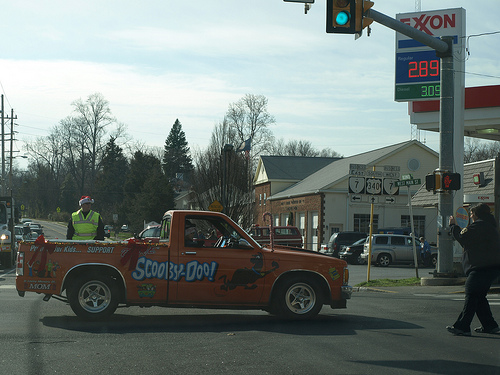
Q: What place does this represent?
A: It represents the road.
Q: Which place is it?
A: It is a road.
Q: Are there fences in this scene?
A: No, there are no fences.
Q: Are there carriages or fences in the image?
A: No, there are no fences or carriages.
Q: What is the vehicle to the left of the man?
A: The vehicle is a car.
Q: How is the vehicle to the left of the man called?
A: The vehicle is a car.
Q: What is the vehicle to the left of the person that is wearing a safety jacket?
A: The vehicle is a car.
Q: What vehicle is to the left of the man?
A: The vehicle is a car.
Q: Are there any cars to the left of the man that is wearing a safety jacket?
A: Yes, there is a car to the left of the man.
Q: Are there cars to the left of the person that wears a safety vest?
A: Yes, there is a car to the left of the man.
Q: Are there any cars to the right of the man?
A: No, the car is to the left of the man.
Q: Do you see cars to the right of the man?
A: No, the car is to the left of the man.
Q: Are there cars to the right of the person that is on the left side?
A: No, the car is to the left of the man.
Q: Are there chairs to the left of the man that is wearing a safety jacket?
A: No, there is a car to the left of the man.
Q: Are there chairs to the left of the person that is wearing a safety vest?
A: No, there is a car to the left of the man.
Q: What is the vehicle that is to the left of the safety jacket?
A: The vehicle is a car.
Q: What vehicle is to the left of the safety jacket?
A: The vehicle is a car.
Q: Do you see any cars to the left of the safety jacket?
A: Yes, there is a car to the left of the safety jacket.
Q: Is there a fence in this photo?
A: No, there are no fences.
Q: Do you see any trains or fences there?
A: No, there are no fences or trains.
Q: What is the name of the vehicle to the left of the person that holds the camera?
A: The vehicle is a car.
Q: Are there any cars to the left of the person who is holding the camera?
A: Yes, there is a car to the left of the person.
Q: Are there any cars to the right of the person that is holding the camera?
A: No, the car is to the left of the person.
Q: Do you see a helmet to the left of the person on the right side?
A: No, there is a car to the left of the person.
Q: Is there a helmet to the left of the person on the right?
A: No, there is a car to the left of the person.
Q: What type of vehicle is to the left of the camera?
A: The vehicle is a car.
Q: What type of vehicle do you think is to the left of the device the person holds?
A: The vehicle is a car.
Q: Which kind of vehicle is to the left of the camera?
A: The vehicle is a car.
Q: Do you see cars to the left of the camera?
A: Yes, there is a car to the left of the camera.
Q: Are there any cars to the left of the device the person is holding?
A: Yes, there is a car to the left of the camera.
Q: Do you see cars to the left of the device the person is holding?
A: Yes, there is a car to the left of the camera.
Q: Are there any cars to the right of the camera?
A: No, the car is to the left of the camera.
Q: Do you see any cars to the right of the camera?
A: No, the car is to the left of the camera.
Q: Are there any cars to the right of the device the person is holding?
A: No, the car is to the left of the camera.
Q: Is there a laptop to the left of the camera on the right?
A: No, there is a car to the left of the camera.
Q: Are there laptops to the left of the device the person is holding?
A: No, there is a car to the left of the camera.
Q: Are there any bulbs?
A: No, there are no bulbs.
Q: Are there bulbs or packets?
A: No, there are no bulbs or packets.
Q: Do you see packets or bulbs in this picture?
A: No, there are no bulbs or packets.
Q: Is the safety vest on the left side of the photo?
A: Yes, the safety vest is on the left of the image.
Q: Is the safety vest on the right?
A: No, the safety vest is on the left of the image.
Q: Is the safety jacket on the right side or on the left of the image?
A: The safety jacket is on the left of the image.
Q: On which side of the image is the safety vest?
A: The safety vest is on the left of the image.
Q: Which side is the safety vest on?
A: The safety vest is on the left of the image.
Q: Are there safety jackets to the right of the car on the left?
A: Yes, there is a safety jacket to the right of the car.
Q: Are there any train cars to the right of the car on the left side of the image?
A: No, there is a safety jacket to the right of the car.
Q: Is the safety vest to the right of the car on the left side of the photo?
A: Yes, the safety vest is to the right of the car.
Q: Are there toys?
A: No, there are no toys.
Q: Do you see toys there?
A: No, there are no toys.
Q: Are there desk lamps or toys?
A: No, there are no toys or desk lamps.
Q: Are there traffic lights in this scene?
A: Yes, there is a traffic light.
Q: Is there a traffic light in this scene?
A: Yes, there is a traffic light.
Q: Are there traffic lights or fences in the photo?
A: Yes, there is a traffic light.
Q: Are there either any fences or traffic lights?
A: Yes, there is a traffic light.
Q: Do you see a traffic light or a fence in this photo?
A: Yes, there is a traffic light.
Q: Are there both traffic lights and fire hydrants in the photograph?
A: No, there is a traffic light but no fire hydrants.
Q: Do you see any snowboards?
A: No, there are no snowboards.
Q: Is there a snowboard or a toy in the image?
A: No, there are no snowboards or toys.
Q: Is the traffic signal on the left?
A: No, the traffic signal is on the right of the image.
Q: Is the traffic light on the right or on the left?
A: The traffic light is on the right of the image.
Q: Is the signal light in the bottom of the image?
A: No, the signal light is in the top of the image.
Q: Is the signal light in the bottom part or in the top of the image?
A: The signal light is in the top of the image.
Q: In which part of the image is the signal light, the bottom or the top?
A: The signal light is in the top of the image.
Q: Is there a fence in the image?
A: No, there are no fences.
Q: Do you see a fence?
A: No, there are no fences.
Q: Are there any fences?
A: No, there are no fences.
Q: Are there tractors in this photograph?
A: No, there are no tractors.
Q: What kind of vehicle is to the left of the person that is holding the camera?
A: The vehicle is a car.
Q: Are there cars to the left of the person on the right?
A: Yes, there is a car to the left of the person.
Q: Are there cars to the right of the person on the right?
A: No, the car is to the left of the person.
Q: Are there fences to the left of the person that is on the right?
A: No, there is a car to the left of the person.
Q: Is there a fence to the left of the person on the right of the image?
A: No, there is a car to the left of the person.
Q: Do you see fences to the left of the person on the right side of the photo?
A: No, there is a car to the left of the person.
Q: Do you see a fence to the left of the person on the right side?
A: No, there is a car to the left of the person.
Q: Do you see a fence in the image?
A: No, there are no fences.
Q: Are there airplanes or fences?
A: No, there are no fences or airplanes.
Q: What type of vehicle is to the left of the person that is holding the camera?
A: The vehicle is a car.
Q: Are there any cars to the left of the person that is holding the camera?
A: Yes, there is a car to the left of the person.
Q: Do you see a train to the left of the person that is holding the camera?
A: No, there is a car to the left of the person.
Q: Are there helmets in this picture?
A: No, there are no helmets.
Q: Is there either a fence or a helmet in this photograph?
A: No, there are no helmets or fences.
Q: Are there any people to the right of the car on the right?
A: Yes, there is a person to the right of the car.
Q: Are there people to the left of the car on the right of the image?
A: No, the person is to the right of the car.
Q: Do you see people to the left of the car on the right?
A: No, the person is to the right of the car.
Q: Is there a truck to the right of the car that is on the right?
A: No, there is a person to the right of the car.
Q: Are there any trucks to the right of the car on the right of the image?
A: No, there is a person to the right of the car.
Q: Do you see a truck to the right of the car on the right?
A: No, there is a person to the right of the car.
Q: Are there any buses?
A: No, there are no buses.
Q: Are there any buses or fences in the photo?
A: No, there are no buses or fences.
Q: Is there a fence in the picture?
A: No, there are no fences.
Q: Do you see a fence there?
A: No, there are no fences.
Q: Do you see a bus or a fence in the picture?
A: No, there are no fences or buses.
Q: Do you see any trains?
A: No, there are no trains.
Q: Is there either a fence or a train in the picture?
A: No, there are no trains or fences.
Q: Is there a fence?
A: No, there are no fences.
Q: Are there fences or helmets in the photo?
A: No, there are no fences or helmets.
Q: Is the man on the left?
A: Yes, the man is on the left of the image.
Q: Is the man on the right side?
A: No, the man is on the left of the image.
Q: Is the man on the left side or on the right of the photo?
A: The man is on the left of the image.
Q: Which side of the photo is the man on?
A: The man is on the left of the image.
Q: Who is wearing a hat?
A: The man is wearing a hat.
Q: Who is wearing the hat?
A: The man is wearing a hat.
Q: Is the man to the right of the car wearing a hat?
A: Yes, the man is wearing a hat.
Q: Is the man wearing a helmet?
A: No, the man is wearing a hat.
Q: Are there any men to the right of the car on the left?
A: Yes, there is a man to the right of the car.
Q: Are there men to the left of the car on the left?
A: No, the man is to the right of the car.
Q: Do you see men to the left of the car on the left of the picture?
A: No, the man is to the right of the car.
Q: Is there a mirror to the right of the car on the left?
A: No, there is a man to the right of the car.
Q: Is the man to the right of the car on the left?
A: Yes, the man is to the right of the car.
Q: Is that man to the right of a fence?
A: No, the man is to the right of the car.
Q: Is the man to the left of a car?
A: No, the man is to the right of a car.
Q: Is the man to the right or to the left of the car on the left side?
A: The man is to the right of the car.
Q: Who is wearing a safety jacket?
A: The man is wearing a safety jacket.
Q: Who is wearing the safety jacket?
A: The man is wearing a safety jacket.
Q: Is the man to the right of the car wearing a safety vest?
A: Yes, the man is wearing a safety vest.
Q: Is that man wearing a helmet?
A: No, the man is wearing a safety vest.